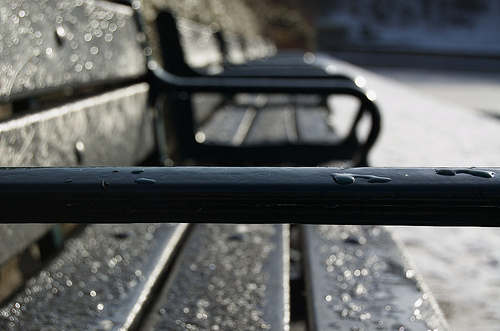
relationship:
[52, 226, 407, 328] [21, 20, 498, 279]
benches on row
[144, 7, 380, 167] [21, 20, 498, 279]
bench on row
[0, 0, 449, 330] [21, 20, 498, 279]
benches on row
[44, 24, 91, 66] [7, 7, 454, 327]
nail on chair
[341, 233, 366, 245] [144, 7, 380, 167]
nail on bench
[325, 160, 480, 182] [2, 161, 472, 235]
rain on arm rest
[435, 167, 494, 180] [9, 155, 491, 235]
rain on armrest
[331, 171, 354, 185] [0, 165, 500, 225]
drops on armrest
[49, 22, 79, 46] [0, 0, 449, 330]
screws in benches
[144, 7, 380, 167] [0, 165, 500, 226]
bench with arm rest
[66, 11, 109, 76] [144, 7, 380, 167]
water on bench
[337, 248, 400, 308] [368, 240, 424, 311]
rain on bench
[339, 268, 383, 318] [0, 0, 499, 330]
rain covered benches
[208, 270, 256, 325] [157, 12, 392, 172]
raindrops on bench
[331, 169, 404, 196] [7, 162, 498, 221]
drops on armrest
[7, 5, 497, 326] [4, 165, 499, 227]
bench with arm rest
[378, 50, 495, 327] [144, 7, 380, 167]
sidewalk in front of bench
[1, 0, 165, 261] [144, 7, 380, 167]
back of bench